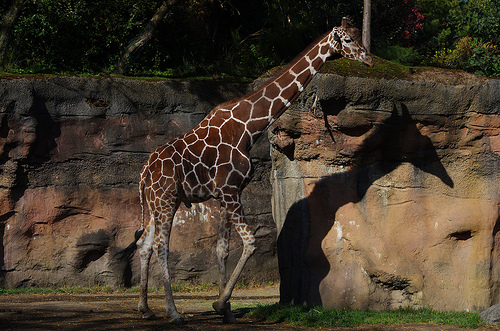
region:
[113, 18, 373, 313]
brown and white giraffe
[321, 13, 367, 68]
large head of giraffe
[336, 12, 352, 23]
small brown horns on giraffe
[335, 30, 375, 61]
white and brown face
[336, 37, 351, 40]
small black eye of giraffe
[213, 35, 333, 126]
long neck of giraffe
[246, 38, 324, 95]
long brown main of giraffe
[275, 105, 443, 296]
large black shadow of giraffe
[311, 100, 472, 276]
large stone wall by giraffe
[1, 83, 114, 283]
black and brown stone wall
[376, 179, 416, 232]
a[prt of a knee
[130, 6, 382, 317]
A giraffe in a zoo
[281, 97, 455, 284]
A shadow of the giraffe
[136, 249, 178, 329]
The giraffes back legs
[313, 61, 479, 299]
A rock that is almost as tall as a giraffe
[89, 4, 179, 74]
Trees growing on top of rocks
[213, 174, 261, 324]
The front legs of a giraffe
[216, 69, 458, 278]
It is a sunny day at the zoo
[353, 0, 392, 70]
A metal pole on the rock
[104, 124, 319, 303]
A giraffe walking around in captivity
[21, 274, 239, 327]
Shadows on the ground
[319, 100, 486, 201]
the shadow is on the rock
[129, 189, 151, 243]
the giraffe has a tail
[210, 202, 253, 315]
the giraffe has front legs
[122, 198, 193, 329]
the iraffe has hind legs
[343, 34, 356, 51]
the giraffe has an eye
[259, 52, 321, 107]
the giraffe has a neck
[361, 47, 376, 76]
the giraffe has a nose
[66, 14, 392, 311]
the giraffe is standing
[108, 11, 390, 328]
the giraffe is tall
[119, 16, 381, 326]
the giraffe is brown and white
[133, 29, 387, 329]
A tall brown and white giraffe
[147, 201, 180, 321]
A tall brown and white giraffe's feet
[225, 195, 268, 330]
A tall brown and white giraffe's feet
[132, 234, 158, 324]
A tall brown and white giraffe's feet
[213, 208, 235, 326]
A tall brown and white giraffe's feet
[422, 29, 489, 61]
A green short bush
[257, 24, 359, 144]
A tall brown and white giraffe's neck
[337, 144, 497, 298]
A brown stone wall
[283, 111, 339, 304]
A brown stone wall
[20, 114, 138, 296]
A brown stone wall